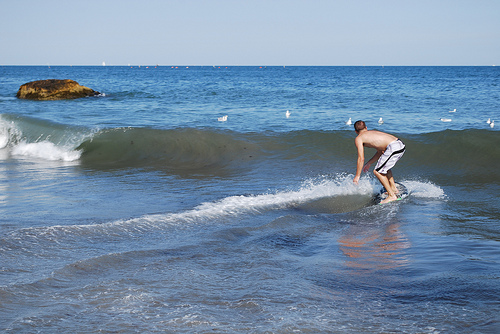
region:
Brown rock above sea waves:
[11, 67, 116, 98]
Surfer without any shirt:
[340, 115, 425, 230]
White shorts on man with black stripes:
[375, 130, 405, 175]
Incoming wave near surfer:
[0, 110, 300, 171]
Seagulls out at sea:
[207, 100, 302, 125]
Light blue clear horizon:
[7, 0, 487, 62]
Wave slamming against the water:
[0, 115, 107, 160]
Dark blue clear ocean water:
[191, 66, 491, 106]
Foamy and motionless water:
[17, 225, 282, 320]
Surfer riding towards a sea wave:
[298, 107, 433, 230]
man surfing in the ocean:
[339, 109, 414, 209]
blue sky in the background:
[4, 6, 488, 43]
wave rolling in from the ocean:
[7, 106, 344, 171]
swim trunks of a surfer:
[373, 134, 406, 176]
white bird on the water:
[374, 111, 389, 128]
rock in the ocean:
[14, 71, 106, 109]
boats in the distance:
[109, 61, 214, 73]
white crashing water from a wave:
[19, 137, 97, 171]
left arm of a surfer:
[348, 140, 367, 190]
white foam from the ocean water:
[216, 196, 278, 207]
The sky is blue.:
[5, 2, 493, 64]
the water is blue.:
[99, 66, 497, 116]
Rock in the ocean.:
[11, 70, 115, 105]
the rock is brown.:
[12, 72, 97, 106]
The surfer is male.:
[342, 114, 416, 218]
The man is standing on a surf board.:
[346, 114, 416, 214]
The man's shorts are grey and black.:
[370, 136, 408, 183]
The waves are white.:
[1, 115, 90, 182]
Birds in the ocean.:
[207, 94, 498, 132]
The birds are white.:
[209, 107, 498, 137]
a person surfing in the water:
[299, 62, 451, 252]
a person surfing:
[297, 100, 447, 230]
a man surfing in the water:
[309, 93, 435, 255]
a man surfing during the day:
[332, 102, 461, 268]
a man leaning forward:
[316, 84, 436, 249]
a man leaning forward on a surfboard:
[296, 84, 486, 214]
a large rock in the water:
[14, 65, 144, 143]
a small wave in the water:
[86, 96, 361, 246]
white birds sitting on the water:
[177, 70, 498, 164]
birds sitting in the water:
[212, 78, 499, 184]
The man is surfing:
[339, 116, 441, 236]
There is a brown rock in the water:
[18, 69, 109, 132]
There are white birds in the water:
[196, 105, 498, 152]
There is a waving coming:
[6, 109, 498, 212]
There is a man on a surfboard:
[325, 116, 440, 245]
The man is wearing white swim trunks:
[346, 113, 413, 226]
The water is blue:
[2, 62, 497, 162]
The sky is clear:
[2, 3, 499, 78]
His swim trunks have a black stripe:
[340, 116, 460, 228]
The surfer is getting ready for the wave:
[332, 108, 449, 250]